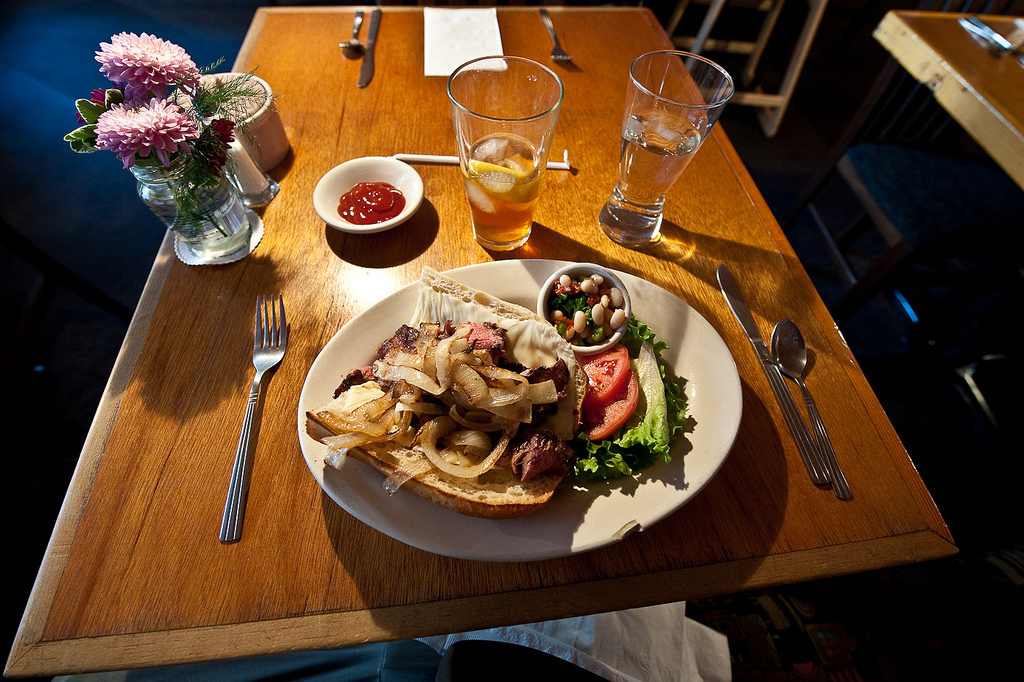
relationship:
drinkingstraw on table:
[384, 140, 575, 173] [3, 3, 969, 678]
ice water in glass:
[612, 104, 708, 223] [590, 40, 731, 247]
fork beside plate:
[206, 289, 286, 540] [277, 253, 764, 560]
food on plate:
[306, 258, 704, 526] [297, 256, 751, 572]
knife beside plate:
[708, 264, 838, 499] [708, 250, 832, 493]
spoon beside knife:
[768, 312, 862, 503] [763, 314, 869, 505]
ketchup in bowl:
[339, 170, 420, 227] [310, 151, 423, 232]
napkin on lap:
[412, 599, 742, 680] [354, 595, 735, 680]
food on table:
[554, 271, 571, 290] [3, 3, 969, 678]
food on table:
[577, 343, 626, 397] [3, 3, 969, 678]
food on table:
[580, 363, 638, 437] [3, 3, 969, 678]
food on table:
[589, 302, 603, 319] [3, 3, 969, 678]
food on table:
[611, 302, 628, 323] [3, 3, 969, 678]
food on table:
[605, 283, 622, 309] [3, 3, 969, 678]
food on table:
[573, 311, 587, 328] [3, 3, 969, 678]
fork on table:
[531, 9, 586, 82] [3, 3, 969, 678]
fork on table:
[227, 285, 292, 554] [3, 3, 969, 678]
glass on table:
[448, 51, 553, 247] [3, 3, 969, 678]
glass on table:
[600, 51, 728, 239] [3, 3, 969, 678]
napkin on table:
[417, 4, 501, 80] [3, 3, 969, 678]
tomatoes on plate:
[582, 349, 646, 438] [277, 253, 764, 560]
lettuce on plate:
[585, 414, 668, 494] [260, 229, 785, 595]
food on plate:
[299, 256, 740, 527] [277, 253, 764, 560]